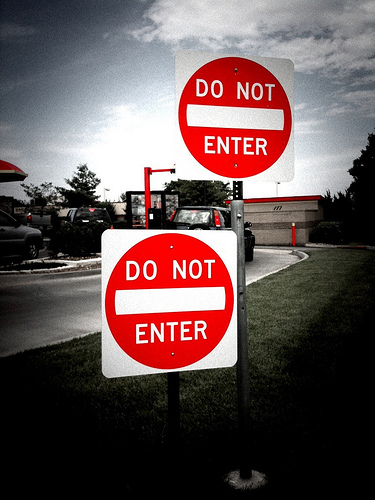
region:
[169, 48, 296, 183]
square white and red metal traffic sign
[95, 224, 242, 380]
square white and red metal traffic sign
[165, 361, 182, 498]
metal sign post attached to sign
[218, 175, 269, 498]
metal sign post attached to sign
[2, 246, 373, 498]
large patch of grass next to fast food restaurant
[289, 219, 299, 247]
red pole near drive through area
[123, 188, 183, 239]
drive through fast food restaurant menu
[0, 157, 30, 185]
red and white umbrella near fast food restaurant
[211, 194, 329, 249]
small gray white and red brick building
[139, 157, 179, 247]
red metal pole next to drive through menu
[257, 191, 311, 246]
building next to the drive thru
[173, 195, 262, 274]
car pulled up to the order board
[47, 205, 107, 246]
car in line at the drive thru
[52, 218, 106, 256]
shrubs separating the two drive thru lanes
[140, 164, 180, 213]
pole with the height accessible to the window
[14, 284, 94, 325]
pavement of the drive thru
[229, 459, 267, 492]
pole cemented in the ground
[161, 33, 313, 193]
white sign on a pole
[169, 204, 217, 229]
windows of a car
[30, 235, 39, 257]
wheel of a car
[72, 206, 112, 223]
windows of a car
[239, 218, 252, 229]
mirror of a car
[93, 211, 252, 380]
traffic sign posting on a pole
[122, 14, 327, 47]
sky full of clouds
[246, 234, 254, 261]
wheel of a car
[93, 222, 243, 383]
sign on the post.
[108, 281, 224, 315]
White bar on the sign.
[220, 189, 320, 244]
building in the background.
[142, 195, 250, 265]
Truck on the road.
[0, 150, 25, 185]
Roof on the building.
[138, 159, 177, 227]
Light pole over street.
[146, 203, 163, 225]
Speaker box on the pole.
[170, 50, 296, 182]
Red circle on the sign.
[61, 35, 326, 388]
two red and white signs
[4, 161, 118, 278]
cars going through a drive-thru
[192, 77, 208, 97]
the letter D on a sign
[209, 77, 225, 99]
the letter O on a sign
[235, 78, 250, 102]
the letter N on a sign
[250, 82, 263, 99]
the letter O on a sign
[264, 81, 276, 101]
the letter T on a sign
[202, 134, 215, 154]
the letter E on a sign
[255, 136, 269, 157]
the letter R on a sign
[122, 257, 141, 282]
the letter D on a sign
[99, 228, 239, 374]
a white and red sign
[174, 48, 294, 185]
a tall white and red sign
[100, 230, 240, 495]
a short red and white sign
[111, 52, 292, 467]
two white and red signs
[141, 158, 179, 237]
a yellow traffic light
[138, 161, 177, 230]
a light on a yellow pole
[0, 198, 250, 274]
cars on a small icy road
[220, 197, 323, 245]
a small gray concrete building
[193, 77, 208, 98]
white letter on sign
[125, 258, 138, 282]
white letter on sign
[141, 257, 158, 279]
white letter on sign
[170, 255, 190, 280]
white letter on sign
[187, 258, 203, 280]
white letter on sign